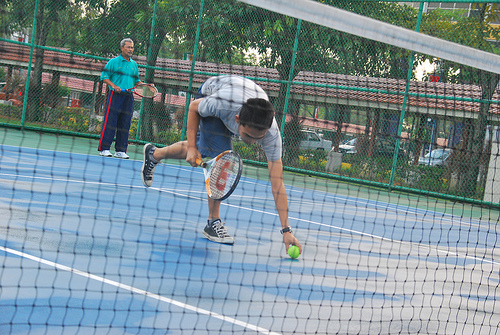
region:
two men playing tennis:
[91, 26, 317, 268]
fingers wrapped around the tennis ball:
[281, 238, 303, 258]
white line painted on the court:
[4, 243, 275, 334]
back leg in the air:
[135, 135, 161, 184]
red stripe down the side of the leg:
[97, 88, 110, 149]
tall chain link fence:
[1, 3, 499, 198]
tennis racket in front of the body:
[107, 77, 164, 102]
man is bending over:
[118, 60, 323, 265]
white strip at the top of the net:
[241, 0, 497, 75]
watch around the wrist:
[277, 223, 294, 235]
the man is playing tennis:
[103, 85, 460, 284]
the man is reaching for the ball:
[248, 200, 331, 300]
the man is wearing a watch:
[267, 206, 329, 266]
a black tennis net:
[192, 229, 267, 285]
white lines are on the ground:
[55, 240, 115, 307]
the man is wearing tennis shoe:
[197, 215, 274, 265]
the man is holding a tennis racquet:
[132, 125, 469, 315]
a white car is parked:
[268, 106, 338, 173]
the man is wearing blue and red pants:
[96, 93, 254, 205]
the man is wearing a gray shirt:
[192, 80, 332, 162]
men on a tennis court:
[79, 14, 411, 311]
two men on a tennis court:
[32, 11, 325, 325]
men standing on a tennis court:
[57, 16, 425, 328]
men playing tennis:
[89, 23, 376, 315]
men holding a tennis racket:
[82, 13, 318, 243]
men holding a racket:
[98, 30, 339, 219]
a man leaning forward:
[147, 45, 343, 265]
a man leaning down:
[97, 91, 307, 251]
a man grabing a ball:
[198, 115, 411, 333]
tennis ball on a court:
[271, 244, 316, 266]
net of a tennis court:
[369, 20, 489, 317]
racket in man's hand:
[195, 144, 246, 208]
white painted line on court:
[33, 248, 149, 308]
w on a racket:
[209, 160, 236, 188]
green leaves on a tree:
[211, 5, 321, 54]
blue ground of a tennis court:
[21, 158, 139, 248]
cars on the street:
[298, 121, 411, 168]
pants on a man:
[98, 85, 134, 153]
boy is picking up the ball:
[171, 48, 333, 278]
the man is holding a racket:
[90, 25, 164, 145]